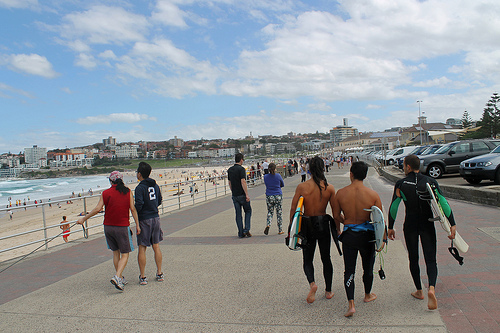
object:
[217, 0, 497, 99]
cloud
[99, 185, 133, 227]
shirt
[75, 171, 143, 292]
she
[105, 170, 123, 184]
hat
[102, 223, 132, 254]
shorts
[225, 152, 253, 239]
people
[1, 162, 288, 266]
shore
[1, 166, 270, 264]
beach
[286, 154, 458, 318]
they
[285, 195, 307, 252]
surfboards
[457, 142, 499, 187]
cars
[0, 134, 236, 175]
buildings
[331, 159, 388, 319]
surfer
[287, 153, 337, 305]
surfer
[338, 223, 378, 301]
wetsuit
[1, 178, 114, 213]
ocean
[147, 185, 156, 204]
number 2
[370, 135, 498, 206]
parking lot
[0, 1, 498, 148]
sky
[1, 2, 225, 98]
clouds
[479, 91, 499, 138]
tree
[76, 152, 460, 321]
several people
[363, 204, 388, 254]
surfboard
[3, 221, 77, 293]
rope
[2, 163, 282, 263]
fence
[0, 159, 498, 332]
street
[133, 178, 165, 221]
man's sweater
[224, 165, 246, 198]
t-shirt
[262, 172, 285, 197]
sweater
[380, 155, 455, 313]
guy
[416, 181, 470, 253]
surfboard